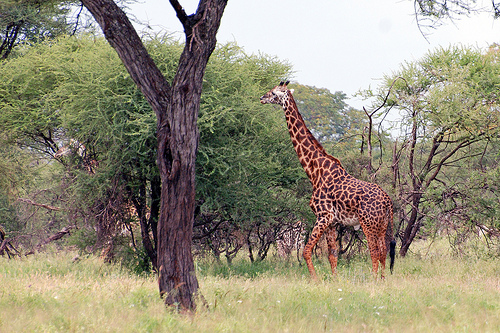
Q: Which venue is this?
A: This is a field.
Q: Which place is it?
A: It is a field.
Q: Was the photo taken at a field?
A: Yes, it was taken in a field.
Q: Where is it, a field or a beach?
A: It is a field.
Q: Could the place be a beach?
A: No, it is a field.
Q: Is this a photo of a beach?
A: No, the picture is showing a field.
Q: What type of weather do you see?
A: It is clear.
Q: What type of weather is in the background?
A: It is clear.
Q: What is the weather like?
A: It is clear.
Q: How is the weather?
A: It is clear.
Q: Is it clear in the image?
A: Yes, it is clear.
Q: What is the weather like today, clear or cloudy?
A: It is clear.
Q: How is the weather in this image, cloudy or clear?
A: It is clear.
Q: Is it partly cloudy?
A: No, it is clear.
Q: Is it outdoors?
A: Yes, it is outdoors.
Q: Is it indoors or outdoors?
A: It is outdoors.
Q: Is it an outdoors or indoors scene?
A: It is outdoors.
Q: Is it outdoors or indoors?
A: It is outdoors.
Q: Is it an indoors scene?
A: No, it is outdoors.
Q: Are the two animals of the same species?
A: Yes, all the animals are giraffes.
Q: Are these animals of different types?
A: No, all the animals are giraffes.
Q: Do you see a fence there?
A: No, there are no fences.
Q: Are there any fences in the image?
A: No, there are no fences.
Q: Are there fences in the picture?
A: No, there are no fences.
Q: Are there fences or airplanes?
A: No, there are no fences or airplanes.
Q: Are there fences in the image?
A: No, there are no fences.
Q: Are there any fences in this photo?
A: No, there are no fences.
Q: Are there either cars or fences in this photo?
A: No, there are no fences or cars.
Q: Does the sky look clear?
A: Yes, the sky is clear.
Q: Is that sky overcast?
A: No, the sky is clear.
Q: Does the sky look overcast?
A: No, the sky is clear.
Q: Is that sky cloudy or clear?
A: The sky is clear.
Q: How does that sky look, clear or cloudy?
A: The sky is clear.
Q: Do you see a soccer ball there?
A: No, there are no soccer balls.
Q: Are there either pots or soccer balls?
A: No, there are no soccer balls or pots.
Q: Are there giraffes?
A: Yes, there is a giraffe.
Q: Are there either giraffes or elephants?
A: Yes, there is a giraffe.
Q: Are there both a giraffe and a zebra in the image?
A: No, there is a giraffe but no zebras.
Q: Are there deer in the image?
A: No, there are no deer.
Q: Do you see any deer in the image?
A: No, there is no deer.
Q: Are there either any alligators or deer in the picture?
A: No, there are no deer or alligators.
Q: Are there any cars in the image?
A: No, there are no cars.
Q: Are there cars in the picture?
A: No, there are no cars.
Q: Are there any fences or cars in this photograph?
A: No, there are no cars or fences.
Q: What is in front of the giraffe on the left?
A: The tree is in front of the giraffe.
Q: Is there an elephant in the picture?
A: No, there are no elephants.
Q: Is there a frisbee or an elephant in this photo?
A: No, there are no elephants or frisbees.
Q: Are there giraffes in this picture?
A: Yes, there is a giraffe.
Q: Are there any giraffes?
A: Yes, there is a giraffe.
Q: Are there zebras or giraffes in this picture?
A: Yes, there is a giraffe.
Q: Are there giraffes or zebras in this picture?
A: Yes, there is a giraffe.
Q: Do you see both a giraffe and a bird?
A: No, there is a giraffe but no birds.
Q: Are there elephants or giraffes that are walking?
A: Yes, the giraffe is walking.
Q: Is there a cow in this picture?
A: No, there are no cows.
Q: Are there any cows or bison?
A: No, there are no cows or bison.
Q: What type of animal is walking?
A: The animal is a giraffe.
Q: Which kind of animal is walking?
A: The animal is a giraffe.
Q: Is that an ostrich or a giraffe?
A: That is a giraffe.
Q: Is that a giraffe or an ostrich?
A: That is a giraffe.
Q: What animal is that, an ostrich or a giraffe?
A: That is a giraffe.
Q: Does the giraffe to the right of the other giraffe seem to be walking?
A: Yes, the giraffe is walking.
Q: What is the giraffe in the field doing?
A: The giraffe is walking.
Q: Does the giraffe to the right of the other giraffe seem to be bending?
A: No, the giraffe is walking.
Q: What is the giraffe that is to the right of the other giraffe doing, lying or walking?
A: The giraffe is walking.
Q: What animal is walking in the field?
A: The giraffe is walking in the field.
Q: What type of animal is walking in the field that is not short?
A: The animal is a giraffe.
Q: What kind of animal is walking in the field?
A: The animal is a giraffe.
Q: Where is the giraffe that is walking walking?
A: The giraffe is walking in the field.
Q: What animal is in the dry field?
A: The giraffe is in the field.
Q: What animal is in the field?
A: The giraffe is in the field.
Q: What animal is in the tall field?
A: The animal is a giraffe.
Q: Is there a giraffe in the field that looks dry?
A: Yes, there is a giraffe in the field.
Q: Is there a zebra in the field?
A: No, there is a giraffe in the field.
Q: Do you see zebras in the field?
A: No, there is a giraffe in the field.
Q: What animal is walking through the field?
A: The animal is a giraffe.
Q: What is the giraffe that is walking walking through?
A: The giraffe is walking through the field.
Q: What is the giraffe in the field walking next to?
A: The giraffe is walking next to the tree.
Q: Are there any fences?
A: No, there are no fences.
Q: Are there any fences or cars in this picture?
A: No, there are no fences or cars.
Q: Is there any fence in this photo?
A: No, there are no fences.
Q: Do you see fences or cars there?
A: No, there are no fences or cars.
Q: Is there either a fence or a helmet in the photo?
A: No, there are no fences or helmets.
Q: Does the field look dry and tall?
A: Yes, the field is dry and tall.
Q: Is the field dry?
A: Yes, the field is dry.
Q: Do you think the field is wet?
A: No, the field is dry.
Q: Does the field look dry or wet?
A: The field is dry.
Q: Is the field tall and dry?
A: Yes, the field is tall and dry.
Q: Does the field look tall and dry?
A: Yes, the field is tall and dry.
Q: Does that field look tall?
A: Yes, the field is tall.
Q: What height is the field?
A: The field is tall.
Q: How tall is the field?
A: The field is tall.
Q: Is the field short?
A: No, the field is tall.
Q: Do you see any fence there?
A: No, there are no fences.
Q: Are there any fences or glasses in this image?
A: No, there are no fences or glasses.